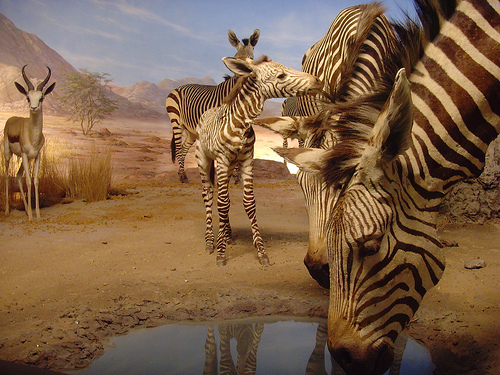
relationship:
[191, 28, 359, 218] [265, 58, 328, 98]
zebra has face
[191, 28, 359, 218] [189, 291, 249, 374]
zebra has shadow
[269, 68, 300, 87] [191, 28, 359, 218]
eye of zebra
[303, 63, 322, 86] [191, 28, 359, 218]
nose of zebra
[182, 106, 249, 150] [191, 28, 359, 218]
skin of zebra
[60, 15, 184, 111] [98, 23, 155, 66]
view of sky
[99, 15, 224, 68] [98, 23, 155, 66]
clouds in sky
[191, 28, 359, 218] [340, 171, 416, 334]
zebra has head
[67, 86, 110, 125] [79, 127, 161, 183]
tree in desert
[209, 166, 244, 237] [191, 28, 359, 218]
leg of zebra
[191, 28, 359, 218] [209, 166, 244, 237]
zebra has leg